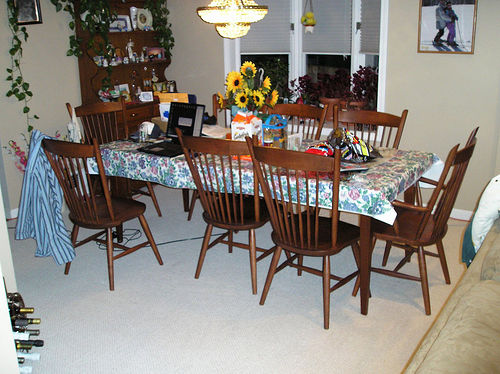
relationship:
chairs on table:
[38, 136, 379, 323] [85, 114, 438, 218]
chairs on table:
[350, 134, 477, 320] [85, 114, 438, 218]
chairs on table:
[204, 88, 421, 152] [85, 114, 438, 218]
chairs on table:
[58, 97, 161, 211] [85, 114, 438, 218]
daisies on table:
[216, 60, 281, 111] [83, 77, 424, 279]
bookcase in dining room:
[75, 1, 172, 152] [6, 8, 482, 352]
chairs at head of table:
[352, 136, 478, 312] [83, 120, 445, 317]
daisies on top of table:
[218, 50, 295, 132] [74, 138, 437, 316]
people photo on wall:
[416, 5, 483, 55] [375, 3, 497, 230]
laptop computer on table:
[137, 97, 206, 163] [40, 97, 447, 319]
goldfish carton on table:
[231, 110, 263, 164] [70, 115, 442, 308]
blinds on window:
[234, 2, 384, 59] [198, 5, 423, 118]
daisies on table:
[216, 60, 281, 111] [160, 114, 492, 209]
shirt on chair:
[10, 120, 86, 263] [29, 141, 152, 279]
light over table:
[197, 4, 270, 40] [33, 95, 478, 333]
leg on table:
[358, 215, 370, 313] [86, 133, 454, 315]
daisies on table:
[216, 60, 281, 111] [90, 118, 439, 213]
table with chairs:
[44, 81, 486, 336] [19, 131, 483, 310]